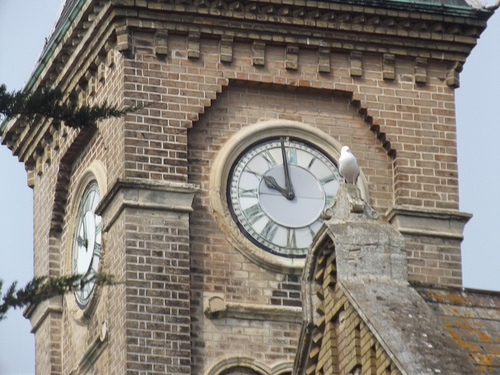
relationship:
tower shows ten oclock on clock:
[3, 0, 494, 375] [228, 142, 366, 260]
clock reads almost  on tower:
[228, 142, 366, 260] [3, 0, 494, 375]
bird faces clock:
[338, 146, 362, 184] [228, 142, 366, 260]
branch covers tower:
[2, 83, 155, 125] [3, 0, 494, 375]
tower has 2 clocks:
[3, 0, 494, 375] [55, 121, 367, 310]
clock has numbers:
[228, 142, 366, 260] [244, 150, 279, 241]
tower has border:
[3, 0, 494, 375] [1, 0, 101, 124]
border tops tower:
[1, 0, 101, 124] [3, 0, 494, 375]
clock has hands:
[228, 142, 366, 260] [265, 141, 294, 201]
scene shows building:
[3, 2, 499, 372] [3, 3, 498, 374]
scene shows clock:
[3, 2, 499, 372] [228, 142, 366, 260]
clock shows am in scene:
[228, 142, 366, 260] [3, 2, 499, 372]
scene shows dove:
[3, 2, 499, 372] [338, 146, 362, 184]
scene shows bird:
[3, 2, 499, 372] [338, 146, 362, 184]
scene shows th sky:
[3, 2, 499, 372] [0, 8, 42, 47]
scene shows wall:
[3, 2, 499, 372] [129, 56, 192, 371]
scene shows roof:
[3, 2, 499, 372] [412, 277, 498, 374]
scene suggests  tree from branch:
[3, 2, 499, 372] [2, 83, 155, 125]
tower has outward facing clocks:
[3, 0, 494, 375] [55, 121, 367, 310]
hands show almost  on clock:
[265, 141, 294, 201] [228, 142, 366, 260]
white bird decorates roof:
[338, 146, 362, 184] [412, 277, 498, 374]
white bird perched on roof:
[338, 146, 362, 184] [300, 184, 499, 374]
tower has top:
[3, 0, 494, 375] [1, 0, 486, 238]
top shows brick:
[1, 0, 486, 238] [136, 76, 179, 153]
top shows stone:
[1, 0, 486, 238] [123, 178, 197, 210]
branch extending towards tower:
[2, 83, 155, 125] [3, 0, 494, 375]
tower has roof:
[3, 0, 494, 375] [2, 0, 494, 158]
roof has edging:
[2, 0, 494, 158] [125, 8, 487, 87]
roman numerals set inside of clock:
[289, 145, 335, 200] [228, 142, 366, 260]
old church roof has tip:
[300, 184, 499, 374] [327, 190, 368, 217]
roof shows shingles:
[412, 277, 498, 374] [435, 291, 500, 317]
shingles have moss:
[435, 291, 500, 317] [436, 289, 466, 304]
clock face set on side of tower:
[228, 142, 366, 260] [3, 0, 494, 375]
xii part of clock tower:
[283, 147, 301, 166] [3, 0, 494, 375]